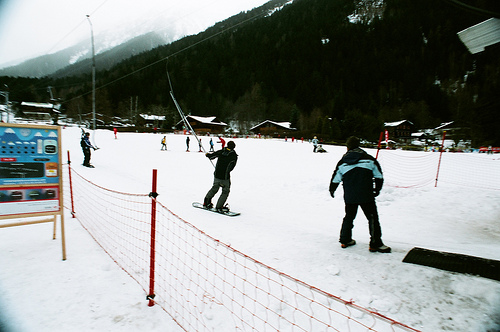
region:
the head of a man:
[223, 133, 241, 153]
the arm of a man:
[204, 146, 224, 165]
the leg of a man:
[214, 180, 233, 210]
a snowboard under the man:
[190, 200, 242, 220]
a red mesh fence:
[56, 146, 423, 330]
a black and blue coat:
[323, 147, 389, 204]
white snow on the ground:
[0, 113, 499, 330]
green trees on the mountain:
[1, 0, 498, 150]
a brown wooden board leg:
[55, 212, 72, 261]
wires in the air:
[60, 1, 295, 111]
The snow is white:
[246, 183, 326, 284]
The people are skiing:
[163, 132, 295, 284]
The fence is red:
[50, 140, 230, 285]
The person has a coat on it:
[293, 112, 419, 277]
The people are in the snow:
[68, 41, 250, 178]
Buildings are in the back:
[143, 96, 392, 208]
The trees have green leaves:
[160, 24, 366, 128]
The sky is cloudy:
[11, 14, 123, 70]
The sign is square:
[0, 122, 99, 294]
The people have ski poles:
[49, 80, 274, 251]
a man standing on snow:
[322, 137, 392, 257]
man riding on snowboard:
[190, 134, 240, 221]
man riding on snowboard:
[78, 126, 100, 172]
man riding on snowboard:
[160, 134, 167, 149]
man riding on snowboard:
[183, 134, 190, 151]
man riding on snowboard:
[195, 137, 203, 152]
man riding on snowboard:
[205, 137, 214, 152]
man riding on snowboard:
[215, 137, 223, 147]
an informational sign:
[0, 121, 84, 263]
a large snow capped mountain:
[2, 0, 499, 113]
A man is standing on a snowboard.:
[188, 133, 245, 230]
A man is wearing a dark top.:
[197, 138, 245, 190]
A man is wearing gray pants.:
[190, 171, 242, 217]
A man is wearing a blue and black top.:
[321, 137, 393, 201]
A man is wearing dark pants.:
[327, 181, 401, 261]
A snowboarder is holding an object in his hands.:
[155, 79, 244, 182]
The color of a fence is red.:
[17, 146, 454, 331]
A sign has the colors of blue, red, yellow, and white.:
[0, 116, 75, 269]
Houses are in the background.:
[2, 93, 497, 156]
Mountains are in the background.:
[0, 0, 499, 142]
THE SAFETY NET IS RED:
[61, 148, 431, 330]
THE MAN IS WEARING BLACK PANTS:
[333, 193, 393, 255]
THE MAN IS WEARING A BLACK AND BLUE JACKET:
[322, 147, 388, 202]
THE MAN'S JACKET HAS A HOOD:
[330, 145, 388, 210]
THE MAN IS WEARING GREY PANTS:
[201, 170, 236, 220]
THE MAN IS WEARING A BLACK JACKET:
[201, 142, 246, 186]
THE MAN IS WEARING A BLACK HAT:
[223, 135, 235, 153]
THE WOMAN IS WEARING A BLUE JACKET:
[310, 137, 320, 147]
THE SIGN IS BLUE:
[0, 117, 67, 219]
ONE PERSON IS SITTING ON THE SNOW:
[316, 142, 329, 154]